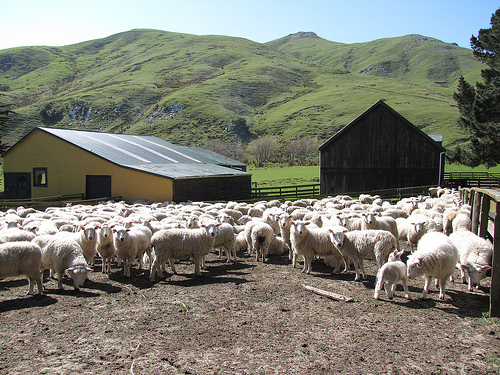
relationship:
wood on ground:
[299, 278, 361, 312] [200, 288, 412, 374]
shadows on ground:
[175, 255, 259, 289] [200, 288, 412, 374]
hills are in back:
[0, 28, 499, 160] [3, 1, 496, 136]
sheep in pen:
[0, 199, 489, 299] [1, 178, 499, 372]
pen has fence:
[1, 178, 499, 372] [244, 181, 329, 203]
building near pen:
[3, 124, 253, 208] [1, 178, 499, 372]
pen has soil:
[1, 178, 499, 372] [146, 294, 303, 364]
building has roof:
[3, 124, 253, 208] [37, 126, 249, 177]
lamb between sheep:
[376, 248, 409, 305] [328, 229, 461, 295]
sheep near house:
[0, 199, 489, 299] [3, 124, 253, 208]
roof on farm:
[37, 126, 249, 177] [3, 124, 253, 208]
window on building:
[31, 163, 50, 189] [3, 124, 253, 208]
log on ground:
[299, 278, 361, 312] [200, 288, 412, 374]